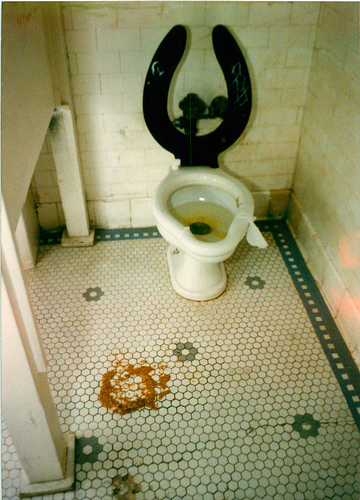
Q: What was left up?
A: Lid to toilet.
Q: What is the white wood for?
A: Privacy wall.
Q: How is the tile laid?
A: In flower pattern.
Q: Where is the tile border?
A: Around the wall.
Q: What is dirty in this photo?
A: White wall tile.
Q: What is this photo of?
A: Public bathroom toilet.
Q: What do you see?
A: A dirty bathroom toilet.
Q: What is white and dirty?
A: Toilet.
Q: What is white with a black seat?
A: Toilet.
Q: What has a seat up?
A: Toilet.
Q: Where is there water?
A: Toilet bowl.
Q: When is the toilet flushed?
A: After use.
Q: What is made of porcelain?
A: Toilet.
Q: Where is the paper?
A: Edge of bowl.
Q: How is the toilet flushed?
A: Handle.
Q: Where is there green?
A: Floor.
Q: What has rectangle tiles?
A: Wall.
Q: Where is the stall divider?
A: Left.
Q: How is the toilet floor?
A: Dirty.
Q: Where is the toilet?
A: In a room.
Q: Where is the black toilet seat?
A: Up.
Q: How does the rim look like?
A: White.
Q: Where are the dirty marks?
A: On the floor.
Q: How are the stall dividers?
A: White and dirty.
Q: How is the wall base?
A: Tiled.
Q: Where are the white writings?
A: On the toilet seat.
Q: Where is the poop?
A: On the floor.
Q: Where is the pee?
A: In the toilet.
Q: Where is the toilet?
A: On the floor.